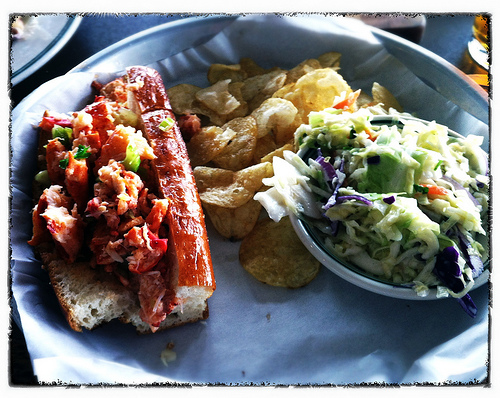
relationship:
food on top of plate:
[37, 52, 499, 331] [21, 16, 484, 381]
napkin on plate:
[6, 264, 498, 378] [21, 16, 484, 381]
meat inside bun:
[99, 185, 161, 278] [31, 78, 212, 337]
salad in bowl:
[305, 120, 487, 282] [287, 122, 492, 301]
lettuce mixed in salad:
[370, 160, 417, 214] [305, 120, 487, 282]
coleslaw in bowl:
[355, 142, 469, 252] [287, 122, 492, 301]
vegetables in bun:
[53, 126, 149, 173] [31, 78, 212, 337]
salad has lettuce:
[305, 120, 487, 282] [370, 160, 417, 214]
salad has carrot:
[305, 120, 487, 282] [419, 183, 450, 199]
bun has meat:
[31, 78, 212, 337] [99, 185, 161, 278]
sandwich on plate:
[37, 79, 207, 327] [21, 16, 484, 381]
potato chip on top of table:
[233, 227, 326, 294] [26, 17, 498, 285]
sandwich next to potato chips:
[37, 79, 207, 327] [190, 58, 319, 268]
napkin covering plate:
[6, 264, 498, 378] [21, 16, 484, 381]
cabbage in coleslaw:
[314, 162, 370, 219] [355, 142, 469, 252]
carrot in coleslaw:
[419, 183, 450, 199] [355, 142, 469, 252]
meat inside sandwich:
[99, 185, 161, 278] [37, 79, 207, 327]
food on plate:
[37, 52, 499, 331] [21, 16, 484, 381]